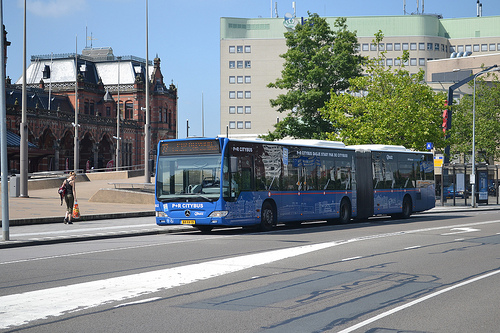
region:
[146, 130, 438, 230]
the buses are blue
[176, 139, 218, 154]
orange letters on buses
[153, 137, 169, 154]
orange numbers on bus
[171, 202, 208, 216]
white letters on the bus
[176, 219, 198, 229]
yellow license plate on bus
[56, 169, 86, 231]
person walking on side of road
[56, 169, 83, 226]
person holding a bag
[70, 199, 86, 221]
the bag is orange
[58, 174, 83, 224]
person wearing high heels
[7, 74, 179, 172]
the building is red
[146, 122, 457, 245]
A blue public bus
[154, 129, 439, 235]
a commuter bus pulling away from the curb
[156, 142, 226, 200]
a windshield on a commuter bus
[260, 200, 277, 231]
a wheel on a commuter bus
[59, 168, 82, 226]
a woman carrying a large bag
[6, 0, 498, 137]
a mostly clear sky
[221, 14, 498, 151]
a large medical building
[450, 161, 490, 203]
a city bus stop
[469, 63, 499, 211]
a tall city lamppost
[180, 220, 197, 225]
a license plate on a bus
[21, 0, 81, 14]
a thin white cloud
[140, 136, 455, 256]
bus on a street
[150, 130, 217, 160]
sign on a bus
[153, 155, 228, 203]
window on a bus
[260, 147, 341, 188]
window on a bus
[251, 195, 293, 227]
tire on a bus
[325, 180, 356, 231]
tire on a bus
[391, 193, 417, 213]
tire on a bus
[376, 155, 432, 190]
window on a bus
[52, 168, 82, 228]
woman walking on a street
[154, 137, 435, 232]
the long blue bus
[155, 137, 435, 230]
the bus on the road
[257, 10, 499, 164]
the green trees near the street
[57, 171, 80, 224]
the woman walking on the street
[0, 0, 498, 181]
the buildings behind the bus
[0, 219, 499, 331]
the white lines on the road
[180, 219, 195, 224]
the license plate on the bus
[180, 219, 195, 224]
the yellow license plate on the bus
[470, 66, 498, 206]
the light post on the sidewalk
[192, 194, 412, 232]
the wheels on the bus